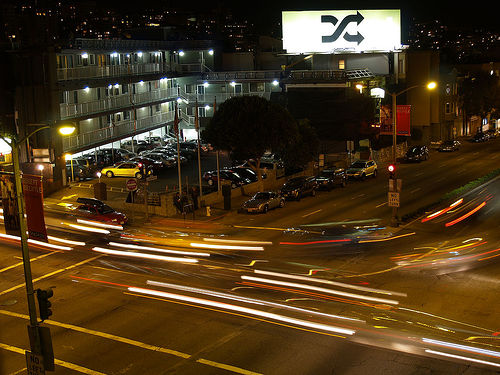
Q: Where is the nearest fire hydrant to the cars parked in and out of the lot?
A: On the corner outside the lot.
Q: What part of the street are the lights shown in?
A: The intersection.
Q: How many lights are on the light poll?
A: Two.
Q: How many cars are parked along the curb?
A: Seven.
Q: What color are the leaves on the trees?
A: Green.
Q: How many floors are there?
A: Three.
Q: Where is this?
A: A busy city street.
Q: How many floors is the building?
A: Three.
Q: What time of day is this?
A: After dark.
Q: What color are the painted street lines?
A: Yellow.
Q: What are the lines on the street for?
A: Crosswalks.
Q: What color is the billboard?
A: Black and white.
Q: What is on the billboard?
A: Two arrows.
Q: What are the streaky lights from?
A: Car headlights and tail lights.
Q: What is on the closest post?
A: A streetlight.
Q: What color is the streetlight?
A: Yellows.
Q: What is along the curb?
A: Parked cars.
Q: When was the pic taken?
A: At night.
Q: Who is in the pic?
A: No one.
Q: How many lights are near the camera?
A: 1.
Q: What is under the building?
A: Cars.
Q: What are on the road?
A: Lines.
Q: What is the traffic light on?
A: Red.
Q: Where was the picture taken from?
A: Over a city block.